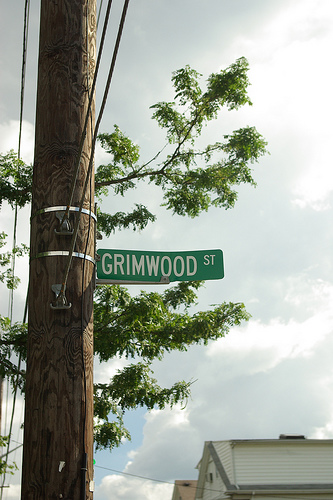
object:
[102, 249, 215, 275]
white lettering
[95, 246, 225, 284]
sign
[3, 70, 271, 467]
tree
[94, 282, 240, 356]
limb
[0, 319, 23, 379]
limb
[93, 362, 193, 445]
limb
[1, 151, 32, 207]
limb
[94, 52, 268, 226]
limb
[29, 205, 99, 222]
silver band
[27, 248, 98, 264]
silver band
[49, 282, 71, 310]
latch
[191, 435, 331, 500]
house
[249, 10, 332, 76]
cloud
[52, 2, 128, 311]
cables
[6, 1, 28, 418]
cables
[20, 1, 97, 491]
pole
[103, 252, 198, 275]
lettering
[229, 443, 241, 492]
gutter